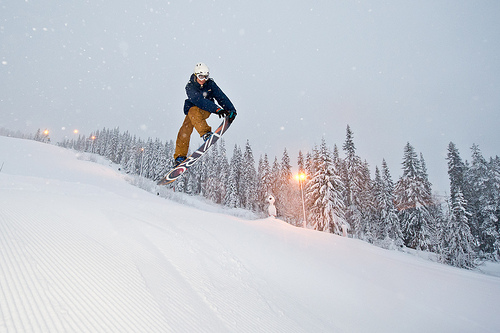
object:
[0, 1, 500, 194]
sky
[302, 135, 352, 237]
trees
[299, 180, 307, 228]
pole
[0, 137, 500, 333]
snow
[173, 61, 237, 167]
man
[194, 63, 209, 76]
helmet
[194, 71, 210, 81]
goggles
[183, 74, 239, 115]
coat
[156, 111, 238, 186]
board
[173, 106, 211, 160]
pants